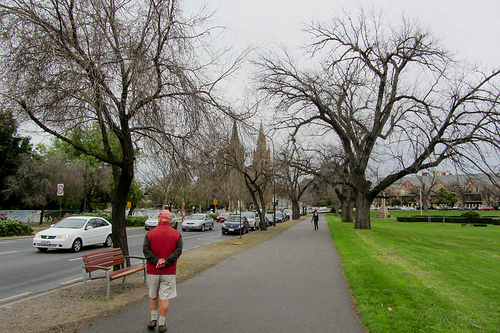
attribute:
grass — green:
[413, 245, 470, 291]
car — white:
[29, 206, 121, 263]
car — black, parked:
[216, 212, 250, 238]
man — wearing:
[143, 209, 183, 331]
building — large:
[191, 109, 361, 249]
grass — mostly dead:
[181, 219, 284, 271]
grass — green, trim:
[370, 225, 498, 331]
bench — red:
[78, 239, 153, 308]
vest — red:
[142, 232, 182, 272]